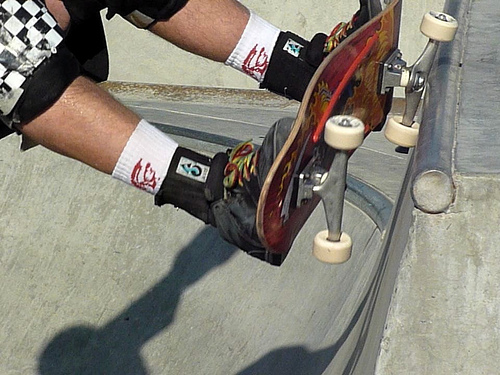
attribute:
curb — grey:
[379, 1, 487, 373]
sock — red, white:
[99, 117, 176, 199]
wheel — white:
[419, 9, 461, 46]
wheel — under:
[381, 115, 422, 150]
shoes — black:
[150, 111, 331, 271]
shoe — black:
[210, 116, 298, 271]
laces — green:
[319, 21, 348, 53]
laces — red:
[219, 136, 374, 216]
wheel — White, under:
[325, 115, 365, 150]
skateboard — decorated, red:
[259, 1, 458, 253]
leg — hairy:
[1, 35, 213, 225]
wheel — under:
[307, 221, 364, 279]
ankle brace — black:
[152, 146, 225, 228]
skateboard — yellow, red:
[245, 8, 452, 269]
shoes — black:
[152, 0, 391, 264]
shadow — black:
[36, 214, 370, 373]